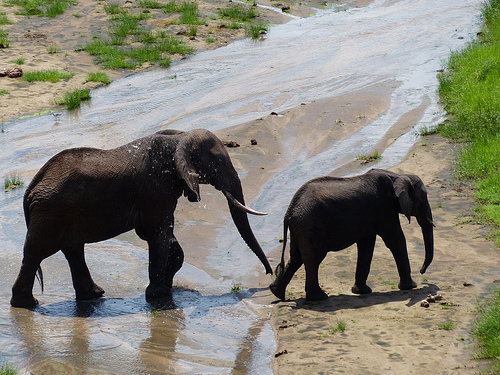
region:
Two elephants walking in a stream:
[3, 125, 438, 316]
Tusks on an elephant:
[227, 191, 269, 218]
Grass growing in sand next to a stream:
[0, 0, 272, 113]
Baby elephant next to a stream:
[267, 165, 437, 308]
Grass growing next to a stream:
[436, 2, 498, 240]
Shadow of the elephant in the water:
[28, 279, 272, 325]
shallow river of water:
[4, 3, 499, 370]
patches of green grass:
[0, 2, 269, 114]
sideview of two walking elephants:
[10, 127, 433, 310]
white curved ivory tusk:
[224, 191, 268, 218]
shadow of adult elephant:
[41, 281, 266, 321]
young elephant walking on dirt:
[269, 171, 434, 303]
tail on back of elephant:
[275, 222, 291, 279]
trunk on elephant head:
[183, 129, 274, 272]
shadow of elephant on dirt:
[281, 280, 437, 315]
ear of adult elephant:
[175, 136, 200, 201]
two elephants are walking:
[21, 129, 466, 356]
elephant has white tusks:
[229, 141, 261, 248]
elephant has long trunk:
[211, 158, 265, 256]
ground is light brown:
[206, 24, 389, 193]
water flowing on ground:
[206, 28, 439, 193]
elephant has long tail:
[21, 138, 73, 305]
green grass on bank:
[38, 2, 218, 115]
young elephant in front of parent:
[266, 188, 456, 313]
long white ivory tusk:
[230, 190, 272, 223]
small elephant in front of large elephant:
[268, 162, 440, 303]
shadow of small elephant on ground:
[262, 279, 446, 316]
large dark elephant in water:
[6, 125, 276, 315]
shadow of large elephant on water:
[15, 280, 272, 325]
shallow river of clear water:
[2, 1, 487, 340]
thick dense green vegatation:
[433, 1, 498, 243]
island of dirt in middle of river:
[103, 76, 404, 284]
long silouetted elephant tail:
[268, 207, 293, 301]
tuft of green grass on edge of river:
[45, 81, 97, 112]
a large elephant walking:
[0, 125, 283, 318]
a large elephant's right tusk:
[214, 177, 274, 226]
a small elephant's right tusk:
[414, 203, 441, 235]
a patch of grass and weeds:
[20, 10, 287, 104]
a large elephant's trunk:
[219, 175, 277, 286]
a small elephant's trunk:
[412, 210, 444, 279]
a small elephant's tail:
[266, 213, 298, 288]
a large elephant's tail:
[7, 190, 52, 305]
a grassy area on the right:
[435, 0, 498, 230]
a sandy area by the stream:
[270, 133, 498, 374]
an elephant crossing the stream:
[9, 128, 272, 310]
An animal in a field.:
[266, 163, 438, 314]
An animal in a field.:
[25, 131, 234, 353]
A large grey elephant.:
[26, 112, 210, 324]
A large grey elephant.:
[267, 147, 440, 344]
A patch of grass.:
[55, 87, 87, 117]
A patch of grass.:
[76, 69, 116, 89]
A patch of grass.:
[25, 65, 61, 89]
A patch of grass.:
[76, 37, 101, 52]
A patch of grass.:
[105, 32, 137, 51]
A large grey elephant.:
[11, 125, 261, 328]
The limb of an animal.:
[301, 235, 333, 293]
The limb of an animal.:
[267, 229, 304, 319]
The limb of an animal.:
[370, 226, 415, 301]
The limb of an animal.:
[142, 211, 187, 332]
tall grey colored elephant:
[6, 120, 280, 325]